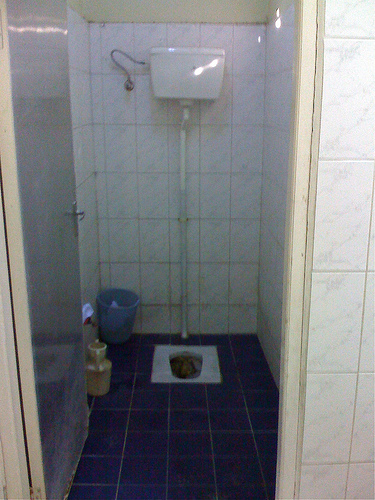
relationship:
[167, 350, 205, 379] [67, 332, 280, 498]
hole in floor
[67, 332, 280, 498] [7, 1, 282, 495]
floor in bathroom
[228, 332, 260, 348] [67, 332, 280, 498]
tile on floor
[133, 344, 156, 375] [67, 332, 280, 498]
tile on floor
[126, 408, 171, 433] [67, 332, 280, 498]
tile on floor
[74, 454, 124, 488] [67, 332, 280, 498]
tile on floor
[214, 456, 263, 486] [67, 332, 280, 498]
tile on floor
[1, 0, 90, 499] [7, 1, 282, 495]
door goes to bathroom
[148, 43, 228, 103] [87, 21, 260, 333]
tank on wall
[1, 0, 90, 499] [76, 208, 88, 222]
door has handle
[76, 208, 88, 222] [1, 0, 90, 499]
handle on door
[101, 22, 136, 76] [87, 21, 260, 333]
tile on wall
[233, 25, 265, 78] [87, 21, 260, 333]
tile on wall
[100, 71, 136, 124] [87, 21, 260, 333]
tile on wall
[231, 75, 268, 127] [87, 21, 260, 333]
tile on wall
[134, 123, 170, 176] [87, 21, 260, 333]
tile on wall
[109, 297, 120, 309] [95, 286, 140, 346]
garbage in basket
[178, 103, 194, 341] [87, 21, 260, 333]
pipe on wall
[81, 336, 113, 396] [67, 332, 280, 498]
jug on floor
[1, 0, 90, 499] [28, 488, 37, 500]
door has hinge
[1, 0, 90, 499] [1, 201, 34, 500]
door has door edge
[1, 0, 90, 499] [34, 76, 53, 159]
door has surface